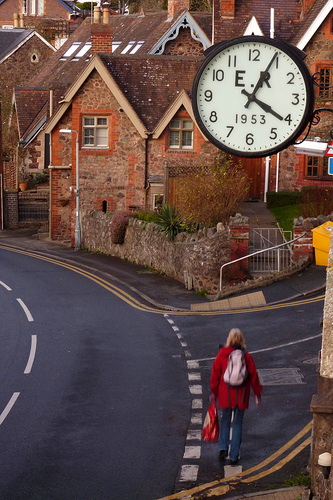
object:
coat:
[210, 346, 264, 410]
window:
[169, 118, 194, 148]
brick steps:
[18, 193, 50, 224]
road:
[0, 243, 327, 499]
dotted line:
[163, 309, 203, 499]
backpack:
[223, 349, 246, 386]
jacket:
[209, 345, 259, 411]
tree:
[152, 197, 193, 243]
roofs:
[50, 2, 332, 143]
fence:
[81, 208, 249, 289]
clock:
[190, 35, 315, 160]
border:
[160, 25, 204, 60]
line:
[1, 242, 327, 315]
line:
[0, 280, 37, 425]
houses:
[0, 0, 333, 298]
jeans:
[218, 408, 244, 461]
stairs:
[16, 189, 50, 233]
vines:
[109, 209, 130, 246]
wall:
[76, 198, 233, 293]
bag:
[202, 398, 220, 443]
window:
[82, 114, 109, 148]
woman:
[209, 329, 263, 466]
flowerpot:
[19, 183, 27, 191]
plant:
[17, 166, 34, 183]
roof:
[0, 23, 58, 71]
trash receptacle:
[310, 220, 330, 267]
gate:
[247, 227, 295, 273]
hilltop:
[0, 188, 333, 363]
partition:
[161, 152, 250, 227]